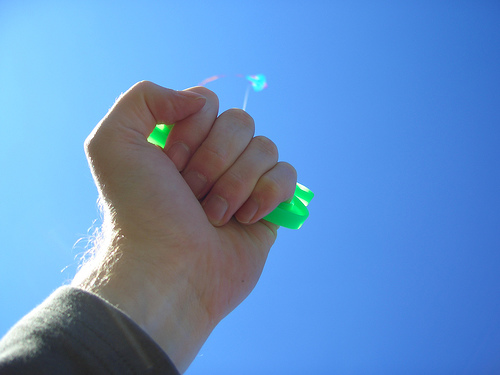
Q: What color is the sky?
A: Blue.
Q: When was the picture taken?
A: During the day.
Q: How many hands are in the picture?
A: One.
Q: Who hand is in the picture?
A: A man.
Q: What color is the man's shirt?
A: Gray.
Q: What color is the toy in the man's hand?
A: Green.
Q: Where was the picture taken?
A: Outside on a sunny day.